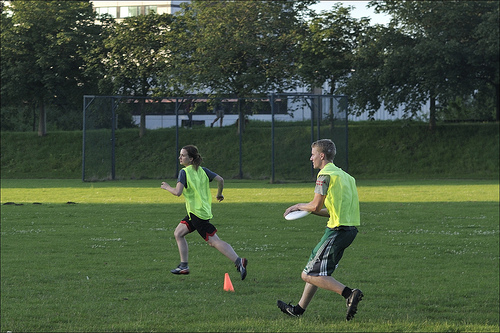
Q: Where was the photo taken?
A: It was taken at the field.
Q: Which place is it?
A: It is a field.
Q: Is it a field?
A: Yes, it is a field.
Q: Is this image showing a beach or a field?
A: It is showing a field.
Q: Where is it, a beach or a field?
A: It is a field.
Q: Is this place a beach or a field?
A: It is a field.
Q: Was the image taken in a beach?
A: No, the picture was taken in a field.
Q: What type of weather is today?
A: It is sunny.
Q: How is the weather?
A: It is sunny.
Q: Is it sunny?
A: Yes, it is sunny.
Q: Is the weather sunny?
A: Yes, it is sunny.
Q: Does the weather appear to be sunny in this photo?
A: Yes, it is sunny.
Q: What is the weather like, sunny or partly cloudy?
A: It is sunny.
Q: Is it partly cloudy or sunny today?
A: It is sunny.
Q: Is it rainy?
A: No, it is sunny.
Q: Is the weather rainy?
A: No, it is sunny.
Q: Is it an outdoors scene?
A: Yes, it is outdoors.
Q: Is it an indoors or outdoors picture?
A: It is outdoors.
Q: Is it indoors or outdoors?
A: It is outdoors.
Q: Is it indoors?
A: No, it is outdoors.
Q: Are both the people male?
A: No, they are both male and female.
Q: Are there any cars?
A: No, there are no cars.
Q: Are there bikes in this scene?
A: No, there are no bikes.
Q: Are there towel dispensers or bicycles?
A: No, there are no bicycles or towel dispensers.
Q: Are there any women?
A: Yes, there is a woman.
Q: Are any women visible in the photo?
A: Yes, there is a woman.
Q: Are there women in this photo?
A: Yes, there is a woman.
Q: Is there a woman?
A: Yes, there is a woman.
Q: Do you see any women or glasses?
A: Yes, there is a woman.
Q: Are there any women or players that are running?
A: Yes, the woman is running.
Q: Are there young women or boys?
A: Yes, there is a young woman.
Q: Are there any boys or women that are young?
A: Yes, the woman is young.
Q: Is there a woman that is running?
A: Yes, there is a woman that is running.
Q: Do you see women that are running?
A: Yes, there is a woman that is running.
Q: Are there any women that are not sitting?
A: Yes, there is a woman that is running.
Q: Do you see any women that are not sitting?
A: Yes, there is a woman that is running .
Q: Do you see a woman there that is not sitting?
A: Yes, there is a woman that is running .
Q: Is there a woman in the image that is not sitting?
A: Yes, there is a woman that is running.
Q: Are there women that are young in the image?
A: Yes, there is a young woman.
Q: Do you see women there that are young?
A: Yes, there is a woman that is young.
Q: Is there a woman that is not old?
A: Yes, there is an young woman.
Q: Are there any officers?
A: No, there are no officers.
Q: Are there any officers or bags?
A: No, there are no officers or bags.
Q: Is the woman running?
A: Yes, the woman is running.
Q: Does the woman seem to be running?
A: Yes, the woman is running.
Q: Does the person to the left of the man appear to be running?
A: Yes, the woman is running.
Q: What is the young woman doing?
A: The woman is running.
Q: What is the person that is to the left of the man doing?
A: The woman is running.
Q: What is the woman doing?
A: The woman is running.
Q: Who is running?
A: The woman is running.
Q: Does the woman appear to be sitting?
A: No, the woman is running.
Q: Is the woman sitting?
A: No, the woman is running.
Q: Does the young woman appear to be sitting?
A: No, the woman is running.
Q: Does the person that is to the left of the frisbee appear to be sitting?
A: No, the woman is running.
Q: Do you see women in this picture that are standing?
A: No, there is a woman but she is running.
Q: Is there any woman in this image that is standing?
A: No, there is a woman but she is running.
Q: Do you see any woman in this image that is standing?
A: No, there is a woman but she is running.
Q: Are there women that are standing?
A: No, there is a woman but she is running.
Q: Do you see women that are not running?
A: No, there is a woman but she is running.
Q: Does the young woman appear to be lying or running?
A: The woman is running.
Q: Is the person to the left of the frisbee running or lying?
A: The woman is running.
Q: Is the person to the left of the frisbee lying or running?
A: The woman is running.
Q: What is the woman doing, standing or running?
A: The woman is running.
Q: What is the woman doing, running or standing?
A: The woman is running.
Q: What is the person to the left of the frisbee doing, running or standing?
A: The woman is running.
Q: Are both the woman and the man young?
A: Yes, both the woman and the man are young.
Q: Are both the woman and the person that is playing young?
A: Yes, both the woman and the man are young.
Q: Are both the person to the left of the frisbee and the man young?
A: Yes, both the woman and the man are young.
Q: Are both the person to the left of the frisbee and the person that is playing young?
A: Yes, both the woman and the man are young.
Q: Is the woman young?
A: Yes, the woman is young.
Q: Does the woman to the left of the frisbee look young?
A: Yes, the woman is young.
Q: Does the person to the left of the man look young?
A: Yes, the woman is young.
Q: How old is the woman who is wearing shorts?
A: The woman is young.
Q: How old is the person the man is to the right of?
A: The woman is young.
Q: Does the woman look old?
A: No, the woman is young.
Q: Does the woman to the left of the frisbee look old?
A: No, the woman is young.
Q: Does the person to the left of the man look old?
A: No, the woman is young.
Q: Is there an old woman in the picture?
A: No, there is a woman but she is young.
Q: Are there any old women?
A: No, there is a woman but she is young.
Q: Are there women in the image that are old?
A: No, there is a woman but she is young.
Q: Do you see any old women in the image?
A: No, there is a woman but she is young.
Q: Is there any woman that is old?
A: No, there is a woman but she is young.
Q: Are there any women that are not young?
A: No, there is a woman but she is young.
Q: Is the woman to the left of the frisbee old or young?
A: The woman is young.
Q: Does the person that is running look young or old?
A: The woman is young.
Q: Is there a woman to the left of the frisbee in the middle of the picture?
A: Yes, there is a woman to the left of the frisbee.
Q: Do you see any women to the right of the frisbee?
A: No, the woman is to the left of the frisbee.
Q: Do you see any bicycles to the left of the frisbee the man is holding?
A: No, there is a woman to the left of the frisbee.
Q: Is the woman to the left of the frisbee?
A: Yes, the woman is to the left of the frisbee.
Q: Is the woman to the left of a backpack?
A: No, the woman is to the left of the frisbee.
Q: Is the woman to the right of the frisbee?
A: No, the woman is to the left of the frisbee.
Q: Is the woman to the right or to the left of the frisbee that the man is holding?
A: The woman is to the left of the frisbee.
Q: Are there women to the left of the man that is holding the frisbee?
A: Yes, there is a woman to the left of the man.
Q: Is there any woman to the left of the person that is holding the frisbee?
A: Yes, there is a woman to the left of the man.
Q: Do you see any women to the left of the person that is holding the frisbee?
A: Yes, there is a woman to the left of the man.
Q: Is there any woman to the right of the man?
A: No, the woman is to the left of the man.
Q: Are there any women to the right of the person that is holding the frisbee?
A: No, the woman is to the left of the man.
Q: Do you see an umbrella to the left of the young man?
A: No, there is a woman to the left of the man.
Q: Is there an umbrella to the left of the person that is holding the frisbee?
A: No, there is a woman to the left of the man.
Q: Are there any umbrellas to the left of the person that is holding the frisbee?
A: No, there is a woman to the left of the man.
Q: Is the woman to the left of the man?
A: Yes, the woman is to the left of the man.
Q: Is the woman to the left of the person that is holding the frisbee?
A: Yes, the woman is to the left of the man.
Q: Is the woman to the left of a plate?
A: No, the woman is to the left of the man.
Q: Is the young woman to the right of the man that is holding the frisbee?
A: No, the woman is to the left of the man.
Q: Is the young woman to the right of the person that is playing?
A: No, the woman is to the left of the man.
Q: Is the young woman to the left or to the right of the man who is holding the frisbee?
A: The woman is to the left of the man.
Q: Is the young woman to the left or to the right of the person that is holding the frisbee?
A: The woman is to the left of the man.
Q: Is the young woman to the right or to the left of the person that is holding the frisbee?
A: The woman is to the left of the man.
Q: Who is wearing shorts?
A: The woman is wearing shorts.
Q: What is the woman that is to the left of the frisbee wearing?
A: The woman is wearing shorts.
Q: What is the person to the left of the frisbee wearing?
A: The woman is wearing shorts.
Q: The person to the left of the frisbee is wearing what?
A: The woman is wearing shorts.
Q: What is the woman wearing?
A: The woman is wearing shorts.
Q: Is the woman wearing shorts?
A: Yes, the woman is wearing shorts.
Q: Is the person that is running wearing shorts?
A: Yes, the woman is wearing shorts.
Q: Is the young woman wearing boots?
A: No, the woman is wearing shorts.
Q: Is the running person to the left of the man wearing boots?
A: No, the woman is wearing shorts.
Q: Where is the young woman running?
A: The woman is running on the field.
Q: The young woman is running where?
A: The woman is running on the field.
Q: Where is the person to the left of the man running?
A: The woman is running on the field.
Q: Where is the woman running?
A: The woman is running on the field.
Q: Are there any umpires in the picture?
A: No, there are no umpires.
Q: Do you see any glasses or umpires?
A: No, there are no umpires or glasses.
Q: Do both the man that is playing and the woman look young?
A: Yes, both the man and the woman are young.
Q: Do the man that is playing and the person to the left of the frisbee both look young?
A: Yes, both the man and the woman are young.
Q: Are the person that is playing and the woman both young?
A: Yes, both the man and the woman are young.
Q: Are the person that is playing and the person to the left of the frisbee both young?
A: Yes, both the man and the woman are young.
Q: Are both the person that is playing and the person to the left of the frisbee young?
A: Yes, both the man and the woman are young.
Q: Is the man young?
A: Yes, the man is young.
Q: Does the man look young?
A: Yes, the man is young.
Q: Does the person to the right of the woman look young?
A: Yes, the man is young.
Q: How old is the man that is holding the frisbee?
A: The man is young.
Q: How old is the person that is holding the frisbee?
A: The man is young.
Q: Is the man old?
A: No, the man is young.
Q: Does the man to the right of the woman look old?
A: No, the man is young.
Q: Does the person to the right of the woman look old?
A: No, the man is young.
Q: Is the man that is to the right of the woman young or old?
A: The man is young.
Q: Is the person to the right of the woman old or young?
A: The man is young.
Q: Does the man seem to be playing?
A: Yes, the man is playing.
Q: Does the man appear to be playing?
A: Yes, the man is playing.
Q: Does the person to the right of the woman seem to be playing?
A: Yes, the man is playing.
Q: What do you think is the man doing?
A: The man is playing.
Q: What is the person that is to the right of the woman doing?
A: The man is playing.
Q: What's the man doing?
A: The man is playing.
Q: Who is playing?
A: The man is playing.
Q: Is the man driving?
A: No, the man is playing.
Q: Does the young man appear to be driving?
A: No, the man is playing.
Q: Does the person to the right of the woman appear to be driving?
A: No, the man is playing.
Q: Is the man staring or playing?
A: The man is playing.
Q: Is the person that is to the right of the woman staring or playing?
A: The man is playing.